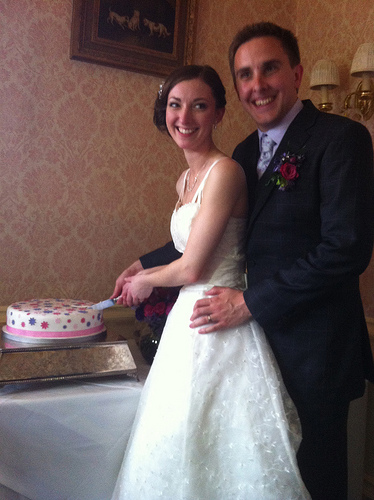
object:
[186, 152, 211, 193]
necklace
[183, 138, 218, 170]
neck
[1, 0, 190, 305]
patterned wallpaper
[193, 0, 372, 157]
patterned wallpaper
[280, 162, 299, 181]
rose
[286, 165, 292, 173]
button hole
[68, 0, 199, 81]
artwork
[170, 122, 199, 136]
smiling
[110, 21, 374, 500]
man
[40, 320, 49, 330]
stars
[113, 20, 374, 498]
couple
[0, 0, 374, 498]
wedding reception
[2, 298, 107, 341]
cake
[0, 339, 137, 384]
tray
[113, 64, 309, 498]
woman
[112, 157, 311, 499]
white dress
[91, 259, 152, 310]
holding knife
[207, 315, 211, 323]
ring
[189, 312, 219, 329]
finger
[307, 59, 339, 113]
lamp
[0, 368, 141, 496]
tablecloth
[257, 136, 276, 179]
tie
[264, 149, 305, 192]
boutonniere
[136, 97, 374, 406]
jacket